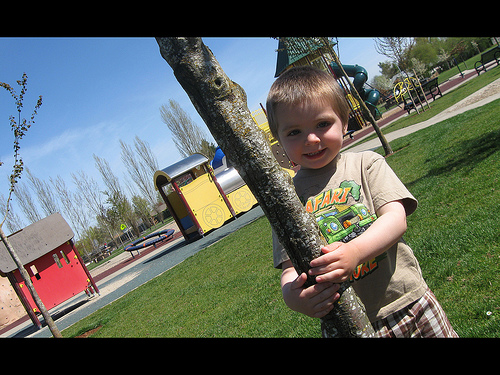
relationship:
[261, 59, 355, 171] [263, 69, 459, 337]
head on kid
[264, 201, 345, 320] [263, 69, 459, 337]
arms on kid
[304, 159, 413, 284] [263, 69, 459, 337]
arms on kid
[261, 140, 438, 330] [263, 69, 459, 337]
shirt on kid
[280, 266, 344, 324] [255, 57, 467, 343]
hand on kid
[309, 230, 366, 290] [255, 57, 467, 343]
hand on kid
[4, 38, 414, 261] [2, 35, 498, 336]
sky above land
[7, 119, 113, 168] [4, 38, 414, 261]
clouds in sky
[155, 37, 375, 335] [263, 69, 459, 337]
tree next to kid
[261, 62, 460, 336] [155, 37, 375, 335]
boy hugging tree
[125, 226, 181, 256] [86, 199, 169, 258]
trampoline near train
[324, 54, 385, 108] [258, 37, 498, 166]
slide on playground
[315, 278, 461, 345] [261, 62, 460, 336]
shorts on boy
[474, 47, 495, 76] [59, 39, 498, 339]
bench in park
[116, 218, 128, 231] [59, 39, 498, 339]
sign in park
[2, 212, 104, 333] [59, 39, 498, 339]
play house in park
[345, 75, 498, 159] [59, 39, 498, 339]
path in park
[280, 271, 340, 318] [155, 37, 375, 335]
hand on tree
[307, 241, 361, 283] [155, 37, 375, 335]
hand on tree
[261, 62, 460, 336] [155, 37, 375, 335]
boy holding tree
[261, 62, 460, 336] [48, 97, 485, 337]
boy standing on grass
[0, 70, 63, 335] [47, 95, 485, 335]
tree growing in field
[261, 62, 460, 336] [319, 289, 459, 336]
boy wearing shorts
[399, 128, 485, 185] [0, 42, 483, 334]
shadow casted on ground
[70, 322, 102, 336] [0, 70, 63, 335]
mulch lying at bottom of tree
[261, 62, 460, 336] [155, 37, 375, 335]
boy gripping tree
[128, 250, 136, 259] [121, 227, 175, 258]
leg holding up trampoline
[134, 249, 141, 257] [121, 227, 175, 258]
leg holding up trampoline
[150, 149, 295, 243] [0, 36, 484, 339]
train sitting in playground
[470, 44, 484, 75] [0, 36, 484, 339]
bench sitting in playground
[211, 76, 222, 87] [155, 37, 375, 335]
hole formed in tree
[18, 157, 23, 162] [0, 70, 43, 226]
leaf growing on tree branch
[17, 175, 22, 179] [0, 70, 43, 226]
leaf growing on tree branch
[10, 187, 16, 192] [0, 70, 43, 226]
leaf growing on tree branch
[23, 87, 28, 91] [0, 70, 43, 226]
leaf growing on tree branch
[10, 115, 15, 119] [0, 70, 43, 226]
leaf growing on tree branch